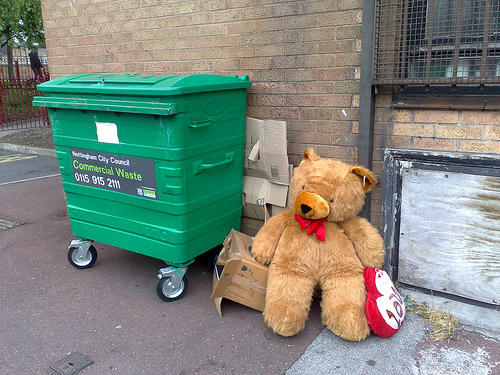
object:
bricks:
[298, 81, 332, 96]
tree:
[0, 0, 47, 52]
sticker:
[68, 146, 160, 202]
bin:
[31, 73, 255, 267]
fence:
[372, 0, 495, 84]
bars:
[361, 36, 500, 88]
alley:
[0, 0, 500, 374]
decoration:
[363, 265, 406, 338]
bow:
[292, 212, 330, 242]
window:
[366, 1, 499, 89]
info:
[66, 149, 156, 198]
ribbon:
[293, 213, 327, 242]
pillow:
[362, 266, 406, 338]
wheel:
[156, 276, 190, 303]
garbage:
[32, 73, 255, 266]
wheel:
[66, 241, 98, 269]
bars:
[375, 0, 498, 37]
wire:
[370, 0, 485, 80]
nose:
[293, 192, 330, 218]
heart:
[363, 267, 407, 338]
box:
[210, 227, 269, 317]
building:
[38, 0, 500, 340]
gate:
[367, 1, 499, 90]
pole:
[355, 1, 381, 221]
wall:
[38, 1, 500, 341]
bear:
[249, 147, 385, 343]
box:
[240, 115, 295, 236]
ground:
[2, 139, 500, 375]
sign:
[68, 145, 160, 201]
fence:
[0, 52, 51, 131]